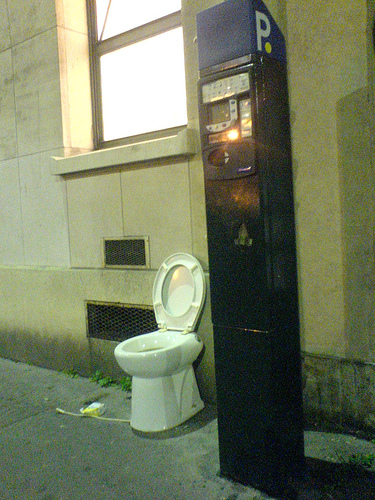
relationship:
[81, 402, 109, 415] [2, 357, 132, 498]
box on ground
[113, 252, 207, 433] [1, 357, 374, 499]
toilet on sidewalk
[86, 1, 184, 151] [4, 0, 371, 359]
window on building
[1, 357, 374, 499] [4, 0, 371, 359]
sidewalk next to building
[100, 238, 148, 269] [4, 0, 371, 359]
vent on building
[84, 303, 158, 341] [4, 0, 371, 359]
vent on building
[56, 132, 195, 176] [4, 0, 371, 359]
window sill on building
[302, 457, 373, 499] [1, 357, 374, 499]
shadow on sidewalk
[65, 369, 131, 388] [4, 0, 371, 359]
weeds on building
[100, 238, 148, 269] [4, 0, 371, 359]
vent on wall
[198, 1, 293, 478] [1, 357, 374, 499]
meter on sidewalk